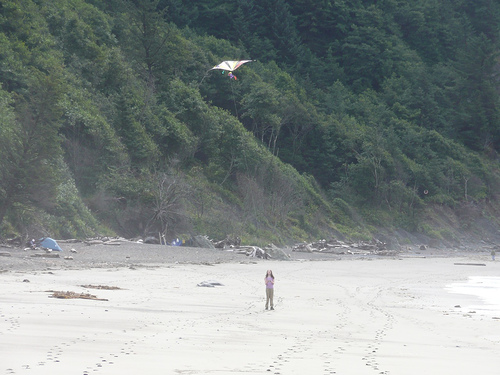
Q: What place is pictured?
A: It is a beach.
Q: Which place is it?
A: It is a beach.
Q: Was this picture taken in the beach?
A: Yes, it was taken in the beach.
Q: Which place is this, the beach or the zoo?
A: It is the beach.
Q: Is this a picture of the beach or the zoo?
A: It is showing the beach.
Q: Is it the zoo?
A: No, it is the beach.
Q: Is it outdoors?
A: Yes, it is outdoors.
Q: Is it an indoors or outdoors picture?
A: It is outdoors.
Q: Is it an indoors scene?
A: No, it is outdoors.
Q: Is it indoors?
A: No, it is outdoors.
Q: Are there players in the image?
A: No, there are no players.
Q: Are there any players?
A: No, there are no players.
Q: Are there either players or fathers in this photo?
A: No, there are no players or fathers.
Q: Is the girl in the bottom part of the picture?
A: Yes, the girl is in the bottom of the image.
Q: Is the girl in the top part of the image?
A: No, the girl is in the bottom of the image.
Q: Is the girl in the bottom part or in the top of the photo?
A: The girl is in the bottom of the image.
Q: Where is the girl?
A: The girl is on the beach.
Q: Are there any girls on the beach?
A: Yes, there is a girl on the beach.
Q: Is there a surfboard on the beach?
A: No, there is a girl on the beach.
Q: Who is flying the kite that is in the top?
A: The girl is flying the kite.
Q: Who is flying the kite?
A: The girl is flying the kite.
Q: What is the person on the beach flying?
A: The girl is flying the kite.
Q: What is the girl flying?
A: The girl is flying the kite.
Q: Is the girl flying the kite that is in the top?
A: Yes, the girl is flying the kite.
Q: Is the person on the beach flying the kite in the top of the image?
A: Yes, the girl is flying the kite.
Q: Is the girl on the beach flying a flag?
A: No, the girl is flying the kite.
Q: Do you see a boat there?
A: No, there are no boats.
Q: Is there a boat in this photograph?
A: No, there are no boats.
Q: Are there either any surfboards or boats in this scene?
A: No, there are no boats or surfboards.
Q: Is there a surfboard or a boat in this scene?
A: No, there are no boats or surfboards.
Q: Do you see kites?
A: Yes, there is a kite.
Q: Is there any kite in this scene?
A: Yes, there is a kite.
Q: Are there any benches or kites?
A: Yes, there is a kite.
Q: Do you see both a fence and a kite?
A: No, there is a kite but no fences.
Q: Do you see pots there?
A: No, there are no pots.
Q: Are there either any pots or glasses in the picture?
A: No, there are no pots or glasses.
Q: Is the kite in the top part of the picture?
A: Yes, the kite is in the top of the image.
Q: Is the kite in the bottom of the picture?
A: No, the kite is in the top of the image.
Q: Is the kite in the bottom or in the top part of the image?
A: The kite is in the top of the image.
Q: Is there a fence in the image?
A: No, there are no fences.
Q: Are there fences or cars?
A: No, there are no fences or cars.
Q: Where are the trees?
A: The trees are on the beach.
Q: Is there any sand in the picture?
A: Yes, there is sand.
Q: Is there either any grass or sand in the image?
A: Yes, there is sand.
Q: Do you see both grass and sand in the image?
A: No, there is sand but no grass.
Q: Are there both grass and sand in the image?
A: No, there is sand but no grass.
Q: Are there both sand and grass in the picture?
A: No, there is sand but no grass.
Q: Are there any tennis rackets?
A: No, there are no tennis rackets.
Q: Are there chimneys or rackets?
A: No, there are no rackets or chimneys.